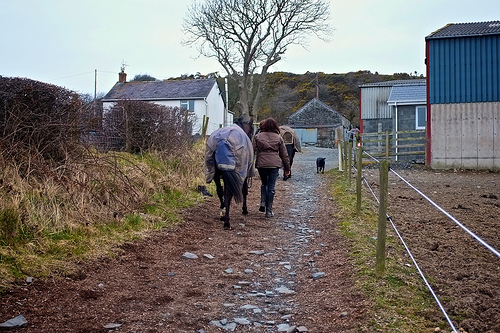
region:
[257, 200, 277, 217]
Woman wearing shoes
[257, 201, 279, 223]
Woman is wearing shoes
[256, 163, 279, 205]
Woman wearing pants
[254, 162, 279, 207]
Woman is wearing pants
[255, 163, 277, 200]
Woman wearing blue pants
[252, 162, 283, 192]
Woman is wearing blue pants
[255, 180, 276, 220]
Woman wearing black boots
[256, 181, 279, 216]
Woman is wearing black boots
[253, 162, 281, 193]
Woman wearing blue jeans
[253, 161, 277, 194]
Woman is wearing blue jeans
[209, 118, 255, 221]
brown horse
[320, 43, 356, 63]
white clouds in blue sky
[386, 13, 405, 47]
white clouds in blue sky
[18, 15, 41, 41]
white clouds in blue sky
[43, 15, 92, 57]
white clouds in blue sky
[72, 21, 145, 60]
white clouds in blue sky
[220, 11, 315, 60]
tall tree bare of leaves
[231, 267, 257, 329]
grey stones in center of path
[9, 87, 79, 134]
brown dead looking bushes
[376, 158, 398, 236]
brown wooden fence poles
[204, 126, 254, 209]
back end of horse in photo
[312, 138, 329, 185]
small black dog in distance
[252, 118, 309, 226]
lady in brown coat leading horse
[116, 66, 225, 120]
white house in distance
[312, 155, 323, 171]
dog on the trail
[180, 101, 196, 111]
window on the house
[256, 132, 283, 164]
jacket on the woman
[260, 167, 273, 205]
pants on the woman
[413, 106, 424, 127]
window on the building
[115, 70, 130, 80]
chimney on the roof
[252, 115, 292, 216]
woman walking on the trail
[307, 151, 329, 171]
black dog on the trail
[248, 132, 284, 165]
purple jacket on the woman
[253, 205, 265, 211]
shoe on the woman's foot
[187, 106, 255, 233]
large brown horse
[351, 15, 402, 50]
white clouds in blue sky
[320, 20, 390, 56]
white clouds in blue sky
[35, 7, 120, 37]
white clouds in blue sky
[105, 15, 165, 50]
white clouds in blue sky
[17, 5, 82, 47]
white clouds in blue sky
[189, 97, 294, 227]
a person walking a horse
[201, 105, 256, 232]
a pack on a horse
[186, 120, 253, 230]
the back of horse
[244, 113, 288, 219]
the back of a lady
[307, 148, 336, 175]
a black dog on path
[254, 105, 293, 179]
the coat is brown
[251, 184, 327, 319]
stones in the path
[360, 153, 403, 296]
a wood fence post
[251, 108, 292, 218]
the lady has brown hair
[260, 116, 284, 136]
the head of a woman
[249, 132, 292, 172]
the jacket of a woman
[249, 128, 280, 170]
the body of a woman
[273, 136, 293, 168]
the right arm of a woman